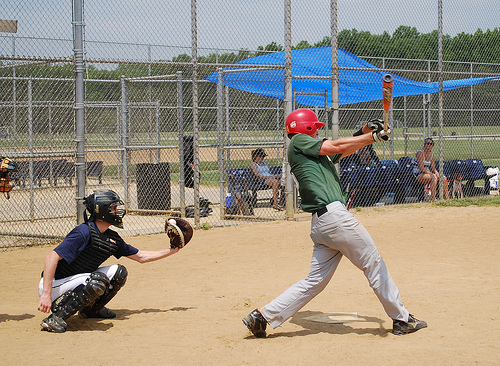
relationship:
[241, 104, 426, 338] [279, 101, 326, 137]
player wears helmet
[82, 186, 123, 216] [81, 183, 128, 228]
helmet on head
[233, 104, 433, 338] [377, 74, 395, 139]
player swing bat